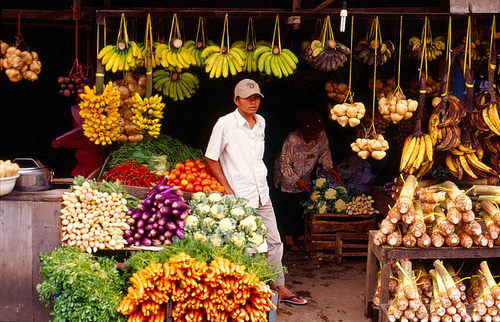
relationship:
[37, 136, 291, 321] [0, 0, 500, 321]
produce in market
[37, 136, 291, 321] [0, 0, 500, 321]
produce at market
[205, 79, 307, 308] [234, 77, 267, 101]
man wearing hat